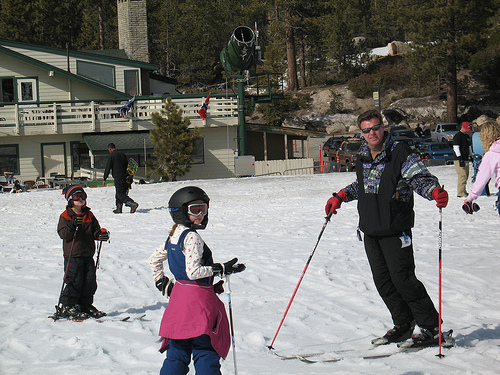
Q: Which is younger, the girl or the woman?
A: The girl is younger than the woman.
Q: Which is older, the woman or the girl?
A: The woman is older than the girl.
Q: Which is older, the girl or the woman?
A: The woman is older than the girl.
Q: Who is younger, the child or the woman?
A: The child is younger than the woman.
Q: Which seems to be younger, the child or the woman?
A: The child is younger than the woman.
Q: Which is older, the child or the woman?
A: The woman is older than the child.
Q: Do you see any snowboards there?
A: Yes, there is a snowboard.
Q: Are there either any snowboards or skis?
A: Yes, there is a snowboard.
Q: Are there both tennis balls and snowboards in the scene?
A: No, there is a snowboard but no tennis balls.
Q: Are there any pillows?
A: No, there are no pillows.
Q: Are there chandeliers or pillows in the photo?
A: No, there are no pillows or chandeliers.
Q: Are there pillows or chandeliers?
A: No, there are no pillows or chandeliers.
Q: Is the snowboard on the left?
A: Yes, the snowboard is on the left of the image.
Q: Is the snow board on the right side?
A: No, the snow board is on the left of the image.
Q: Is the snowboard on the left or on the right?
A: The snowboard is on the left of the image.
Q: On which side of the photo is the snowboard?
A: The snowboard is on the left of the image.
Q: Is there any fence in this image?
A: No, there are no fences.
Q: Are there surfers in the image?
A: No, there are no surfers.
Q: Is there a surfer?
A: No, there are no surfers.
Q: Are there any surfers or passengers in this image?
A: No, there are no surfers or passengers.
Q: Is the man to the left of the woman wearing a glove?
A: Yes, the man is wearing a glove.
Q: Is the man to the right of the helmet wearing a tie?
A: No, the man is wearing a glove.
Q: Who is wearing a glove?
A: The man is wearing a glove.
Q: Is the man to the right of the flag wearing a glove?
A: Yes, the man is wearing a glove.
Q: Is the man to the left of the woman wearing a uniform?
A: No, the man is wearing a glove.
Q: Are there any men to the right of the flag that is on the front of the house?
A: Yes, there is a man to the right of the flag.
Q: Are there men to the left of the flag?
A: No, the man is to the right of the flag.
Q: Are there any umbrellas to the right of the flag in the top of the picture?
A: No, there is a man to the right of the flag.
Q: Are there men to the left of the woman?
A: Yes, there is a man to the left of the woman.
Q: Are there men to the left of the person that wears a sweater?
A: Yes, there is a man to the left of the woman.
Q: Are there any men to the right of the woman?
A: No, the man is to the left of the woman.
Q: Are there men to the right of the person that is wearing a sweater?
A: No, the man is to the left of the woman.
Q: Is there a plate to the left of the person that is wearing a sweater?
A: No, there is a man to the left of the woman.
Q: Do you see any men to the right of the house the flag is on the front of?
A: Yes, there is a man to the right of the house.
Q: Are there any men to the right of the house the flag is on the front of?
A: Yes, there is a man to the right of the house.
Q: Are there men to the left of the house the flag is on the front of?
A: No, the man is to the right of the house.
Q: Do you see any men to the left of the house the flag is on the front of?
A: No, the man is to the right of the house.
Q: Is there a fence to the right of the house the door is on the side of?
A: No, there is a man to the right of the house.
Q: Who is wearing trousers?
A: The man is wearing trousers.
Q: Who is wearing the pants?
A: The man is wearing trousers.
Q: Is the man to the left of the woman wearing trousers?
A: Yes, the man is wearing trousers.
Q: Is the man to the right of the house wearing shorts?
A: No, the man is wearing trousers.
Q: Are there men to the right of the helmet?
A: Yes, there is a man to the right of the helmet.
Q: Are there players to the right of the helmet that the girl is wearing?
A: No, there is a man to the right of the helmet.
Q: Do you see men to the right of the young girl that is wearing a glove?
A: Yes, there is a man to the right of the girl.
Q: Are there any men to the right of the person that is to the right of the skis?
A: Yes, there is a man to the right of the girl.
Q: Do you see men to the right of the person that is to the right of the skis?
A: Yes, there is a man to the right of the girl.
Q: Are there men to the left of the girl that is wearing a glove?
A: No, the man is to the right of the girl.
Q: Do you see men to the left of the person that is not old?
A: No, the man is to the right of the girl.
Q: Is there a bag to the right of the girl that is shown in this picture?
A: No, there is a man to the right of the girl.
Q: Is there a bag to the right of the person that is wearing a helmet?
A: No, there is a man to the right of the girl.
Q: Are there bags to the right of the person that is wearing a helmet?
A: No, there is a man to the right of the girl.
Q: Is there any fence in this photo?
A: No, there are no fences.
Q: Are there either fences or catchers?
A: No, there are no fences or catchers.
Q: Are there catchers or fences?
A: No, there are no fences or catchers.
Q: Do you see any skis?
A: Yes, there are skis.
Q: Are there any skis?
A: Yes, there are skis.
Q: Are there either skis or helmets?
A: Yes, there are skis.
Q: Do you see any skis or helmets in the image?
A: Yes, there are skis.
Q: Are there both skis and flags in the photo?
A: Yes, there are both skis and a flag.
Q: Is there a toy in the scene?
A: No, there are no toys.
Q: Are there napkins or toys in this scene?
A: No, there are no toys or napkins.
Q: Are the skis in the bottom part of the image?
A: Yes, the skis are in the bottom of the image.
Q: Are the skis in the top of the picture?
A: No, the skis are in the bottom of the image.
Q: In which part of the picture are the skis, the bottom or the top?
A: The skis are in the bottom of the image.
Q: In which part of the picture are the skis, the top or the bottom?
A: The skis are in the bottom of the image.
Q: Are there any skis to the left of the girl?
A: Yes, there are skis to the left of the girl.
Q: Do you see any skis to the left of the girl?
A: Yes, there are skis to the left of the girl.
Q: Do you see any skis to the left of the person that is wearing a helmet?
A: Yes, there are skis to the left of the girl.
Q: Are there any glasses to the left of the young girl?
A: No, there are skis to the left of the girl.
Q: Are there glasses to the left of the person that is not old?
A: No, there are skis to the left of the girl.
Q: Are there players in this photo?
A: No, there are no players.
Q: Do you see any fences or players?
A: No, there are no players or fences.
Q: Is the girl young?
A: Yes, the girl is young.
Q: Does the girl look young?
A: Yes, the girl is young.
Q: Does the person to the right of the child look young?
A: Yes, the girl is young.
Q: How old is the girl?
A: The girl is young.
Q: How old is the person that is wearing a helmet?
A: The girl is young.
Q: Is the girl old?
A: No, the girl is young.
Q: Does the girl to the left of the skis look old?
A: No, the girl is young.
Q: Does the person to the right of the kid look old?
A: No, the girl is young.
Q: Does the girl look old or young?
A: The girl is young.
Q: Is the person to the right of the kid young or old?
A: The girl is young.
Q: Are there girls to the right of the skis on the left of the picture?
A: Yes, there is a girl to the right of the skis.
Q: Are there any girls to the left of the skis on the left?
A: No, the girl is to the right of the skis.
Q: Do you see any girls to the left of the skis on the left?
A: No, the girl is to the right of the skis.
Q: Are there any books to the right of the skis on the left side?
A: No, there is a girl to the right of the skis.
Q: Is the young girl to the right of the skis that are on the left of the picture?
A: Yes, the girl is to the right of the skis.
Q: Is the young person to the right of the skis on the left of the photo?
A: Yes, the girl is to the right of the skis.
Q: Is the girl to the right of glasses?
A: No, the girl is to the right of the skis.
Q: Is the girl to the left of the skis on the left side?
A: No, the girl is to the right of the skis.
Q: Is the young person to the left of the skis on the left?
A: No, the girl is to the right of the skis.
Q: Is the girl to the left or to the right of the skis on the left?
A: The girl is to the right of the skis.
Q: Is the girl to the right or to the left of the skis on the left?
A: The girl is to the right of the skis.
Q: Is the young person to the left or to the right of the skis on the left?
A: The girl is to the right of the skis.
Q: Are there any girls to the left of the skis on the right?
A: Yes, there is a girl to the left of the skis.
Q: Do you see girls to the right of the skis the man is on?
A: No, the girl is to the left of the skis.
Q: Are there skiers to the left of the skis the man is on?
A: No, there is a girl to the left of the skis.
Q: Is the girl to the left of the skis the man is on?
A: Yes, the girl is to the left of the skis.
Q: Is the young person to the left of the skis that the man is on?
A: Yes, the girl is to the left of the skis.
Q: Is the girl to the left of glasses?
A: No, the girl is to the left of the skis.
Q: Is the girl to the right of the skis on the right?
A: No, the girl is to the left of the skis.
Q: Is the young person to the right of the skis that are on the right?
A: No, the girl is to the left of the skis.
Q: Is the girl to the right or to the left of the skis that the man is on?
A: The girl is to the left of the skis.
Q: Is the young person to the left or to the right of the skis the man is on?
A: The girl is to the left of the skis.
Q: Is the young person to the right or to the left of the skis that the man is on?
A: The girl is to the left of the skis.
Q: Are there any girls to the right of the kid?
A: Yes, there is a girl to the right of the kid.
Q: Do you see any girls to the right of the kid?
A: Yes, there is a girl to the right of the kid.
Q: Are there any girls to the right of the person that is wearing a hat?
A: Yes, there is a girl to the right of the kid.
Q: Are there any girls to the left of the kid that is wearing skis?
A: No, the girl is to the right of the kid.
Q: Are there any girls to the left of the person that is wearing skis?
A: No, the girl is to the right of the kid.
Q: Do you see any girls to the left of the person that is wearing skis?
A: No, the girl is to the right of the kid.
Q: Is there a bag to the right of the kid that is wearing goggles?
A: No, there is a girl to the right of the child.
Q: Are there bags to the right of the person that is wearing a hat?
A: No, there is a girl to the right of the child.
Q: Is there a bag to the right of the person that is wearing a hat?
A: No, there is a girl to the right of the child.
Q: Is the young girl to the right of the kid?
A: Yes, the girl is to the right of the kid.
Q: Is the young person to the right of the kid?
A: Yes, the girl is to the right of the kid.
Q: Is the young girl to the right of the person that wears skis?
A: Yes, the girl is to the right of the kid.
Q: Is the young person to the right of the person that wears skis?
A: Yes, the girl is to the right of the kid.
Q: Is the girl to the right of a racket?
A: No, the girl is to the right of the kid.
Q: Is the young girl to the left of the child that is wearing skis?
A: No, the girl is to the right of the kid.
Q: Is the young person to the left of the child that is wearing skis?
A: No, the girl is to the right of the kid.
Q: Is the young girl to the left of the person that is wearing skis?
A: No, the girl is to the right of the kid.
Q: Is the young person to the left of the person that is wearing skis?
A: No, the girl is to the right of the kid.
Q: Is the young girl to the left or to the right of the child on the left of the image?
A: The girl is to the right of the kid.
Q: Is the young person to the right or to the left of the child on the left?
A: The girl is to the right of the kid.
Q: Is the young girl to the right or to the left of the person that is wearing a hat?
A: The girl is to the right of the kid.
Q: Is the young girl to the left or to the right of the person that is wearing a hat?
A: The girl is to the right of the kid.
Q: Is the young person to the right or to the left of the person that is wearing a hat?
A: The girl is to the right of the kid.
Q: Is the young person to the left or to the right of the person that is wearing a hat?
A: The girl is to the right of the kid.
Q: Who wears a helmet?
A: The girl wears a helmet.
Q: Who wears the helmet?
A: The girl wears a helmet.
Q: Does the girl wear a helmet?
A: Yes, the girl wears a helmet.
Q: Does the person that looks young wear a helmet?
A: Yes, the girl wears a helmet.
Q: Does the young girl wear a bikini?
A: No, the girl wears a helmet.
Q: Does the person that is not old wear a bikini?
A: No, the girl wears a helmet.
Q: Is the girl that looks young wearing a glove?
A: Yes, the girl is wearing a glove.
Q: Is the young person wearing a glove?
A: Yes, the girl is wearing a glove.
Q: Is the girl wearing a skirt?
A: No, the girl is wearing a glove.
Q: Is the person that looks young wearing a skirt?
A: No, the girl is wearing a glove.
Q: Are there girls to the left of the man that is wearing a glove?
A: Yes, there is a girl to the left of the man.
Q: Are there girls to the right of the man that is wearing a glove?
A: No, the girl is to the left of the man.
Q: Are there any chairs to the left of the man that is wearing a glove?
A: No, there is a girl to the left of the man.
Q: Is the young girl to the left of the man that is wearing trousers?
A: Yes, the girl is to the left of the man.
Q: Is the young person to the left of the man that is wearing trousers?
A: Yes, the girl is to the left of the man.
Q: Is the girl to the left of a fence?
A: No, the girl is to the left of the man.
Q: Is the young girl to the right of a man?
A: No, the girl is to the left of a man.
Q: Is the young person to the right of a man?
A: No, the girl is to the left of a man.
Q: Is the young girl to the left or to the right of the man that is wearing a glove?
A: The girl is to the left of the man.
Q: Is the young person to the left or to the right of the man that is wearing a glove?
A: The girl is to the left of the man.